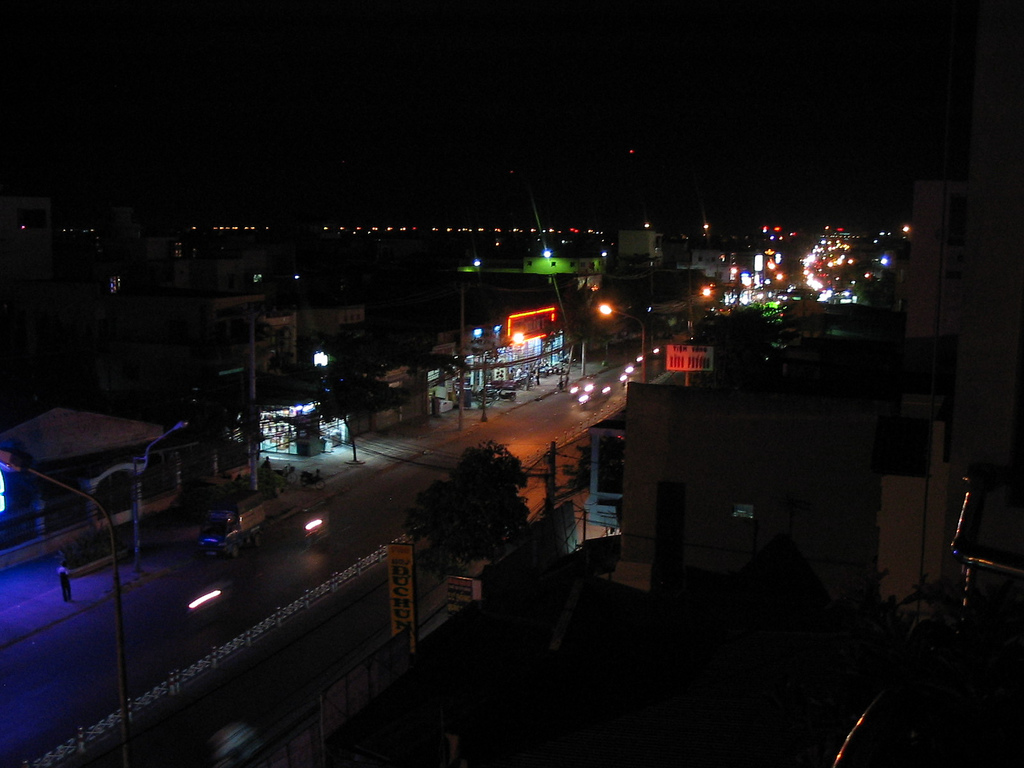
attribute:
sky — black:
[0, 4, 1024, 276]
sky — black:
[343, 30, 701, 250]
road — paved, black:
[55, 242, 824, 762]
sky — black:
[73, 24, 266, 160]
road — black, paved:
[10, 354, 652, 761]